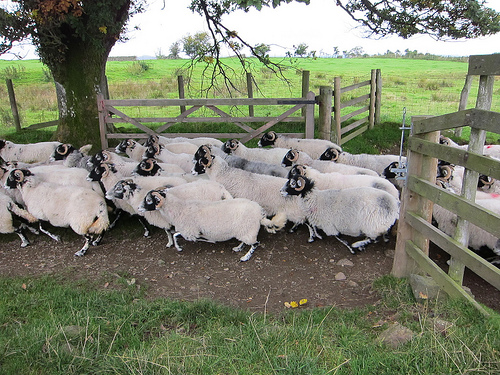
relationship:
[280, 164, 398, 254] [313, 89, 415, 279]
sheep running out gate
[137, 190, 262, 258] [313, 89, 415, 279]
sheep running out gate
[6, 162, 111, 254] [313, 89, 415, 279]
sheep running out gate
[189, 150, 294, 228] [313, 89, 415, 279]
sheep running out gate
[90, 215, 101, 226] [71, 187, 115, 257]
yellow spot on butt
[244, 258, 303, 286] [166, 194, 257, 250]
dirt under sheep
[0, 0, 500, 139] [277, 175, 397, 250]
large tree near sheep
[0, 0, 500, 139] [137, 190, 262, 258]
large tree near sheep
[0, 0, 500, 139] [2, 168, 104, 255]
large tree near sheep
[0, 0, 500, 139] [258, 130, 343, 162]
large tree near sheep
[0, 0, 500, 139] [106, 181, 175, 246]
large tree near sheep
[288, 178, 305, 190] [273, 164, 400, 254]
horn of ram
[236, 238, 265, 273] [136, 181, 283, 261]
leg of ram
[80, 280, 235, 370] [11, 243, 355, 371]
grass on ground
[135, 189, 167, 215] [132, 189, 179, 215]
head of a ram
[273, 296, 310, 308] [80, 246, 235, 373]
flowers on ground